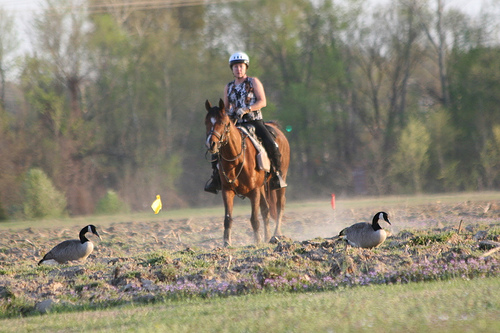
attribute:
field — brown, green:
[3, 193, 500, 332]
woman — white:
[211, 49, 295, 168]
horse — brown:
[201, 95, 307, 237]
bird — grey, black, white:
[340, 210, 403, 251]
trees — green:
[11, 4, 482, 194]